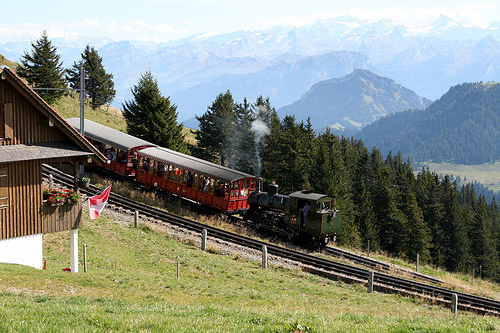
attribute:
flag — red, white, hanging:
[88, 183, 113, 220]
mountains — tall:
[0, 15, 500, 165]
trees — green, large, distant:
[16, 28, 500, 286]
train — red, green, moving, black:
[57, 117, 261, 214]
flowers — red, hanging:
[40, 185, 81, 205]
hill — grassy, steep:
[0, 53, 500, 333]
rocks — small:
[44, 179, 306, 270]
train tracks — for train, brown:
[42, 162, 499, 315]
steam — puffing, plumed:
[225, 105, 272, 178]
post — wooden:
[70, 229, 79, 273]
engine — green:
[244, 181, 341, 249]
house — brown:
[0, 65, 110, 273]